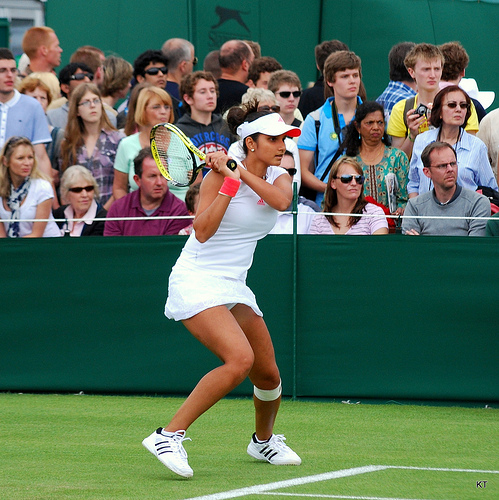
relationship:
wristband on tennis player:
[209, 169, 261, 215] [81, 86, 386, 460]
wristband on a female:
[218, 175, 240, 198] [141, 98, 302, 479]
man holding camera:
[387, 39, 459, 135] [409, 100, 432, 125]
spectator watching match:
[0, 25, 499, 240] [26, 28, 478, 482]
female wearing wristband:
[141, 98, 302, 479] [191, 158, 272, 228]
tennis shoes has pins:
[138, 419, 304, 479] [139, 420, 302, 480]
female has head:
[132, 102, 308, 477] [222, 95, 303, 174]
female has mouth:
[141, 98, 302, 479] [269, 150, 281, 166]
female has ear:
[141, 98, 302, 479] [244, 135, 255, 152]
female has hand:
[141, 98, 302, 479] [213, 154, 240, 185]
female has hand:
[141, 98, 302, 479] [205, 147, 231, 170]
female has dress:
[141, 98, 302, 479] [163, 159, 277, 315]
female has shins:
[141, 98, 302, 479] [152, 355, 288, 444]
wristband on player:
[218, 175, 240, 198] [70, 63, 355, 487]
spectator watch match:
[0, 25, 499, 240] [102, 73, 394, 493]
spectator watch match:
[400, 138, 491, 230] [102, 73, 394, 493]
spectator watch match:
[0, 25, 499, 240] [90, 81, 367, 496]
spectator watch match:
[0, 25, 499, 240] [77, 97, 416, 487]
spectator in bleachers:
[0, 25, 499, 240] [2, 212, 498, 402]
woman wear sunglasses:
[311, 144, 396, 243] [332, 168, 370, 186]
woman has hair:
[39, 158, 103, 249] [57, 158, 99, 201]